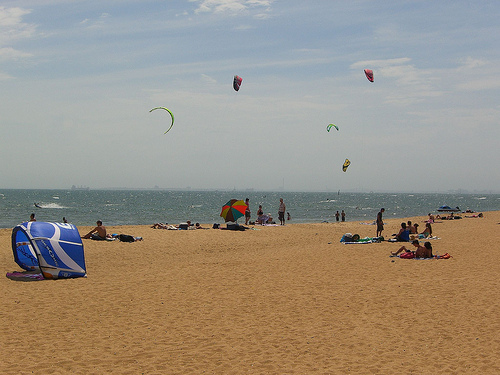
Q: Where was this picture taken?
A: A beach.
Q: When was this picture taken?
A: Daytime.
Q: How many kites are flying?
A: Five.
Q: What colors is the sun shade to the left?
A: Blue and white.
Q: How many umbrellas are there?
A: One.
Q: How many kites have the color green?
A: Two.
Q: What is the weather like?
A: Sunny.